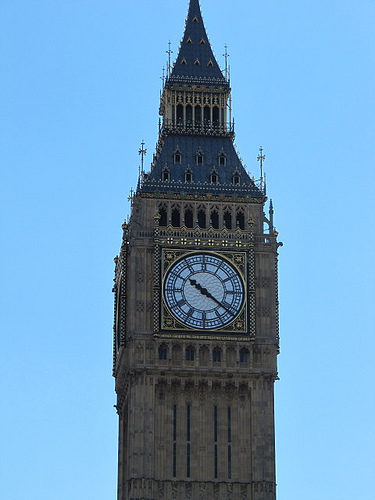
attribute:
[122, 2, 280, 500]
tower — large, building, made with brick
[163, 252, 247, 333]
clock — analog, big, for telling time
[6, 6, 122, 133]
sky — blue, cloudless, clear, clear blue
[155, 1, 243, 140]
steeple — made of stone, blue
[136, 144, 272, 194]
crosses — tall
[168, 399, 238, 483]
vertical openings — slits